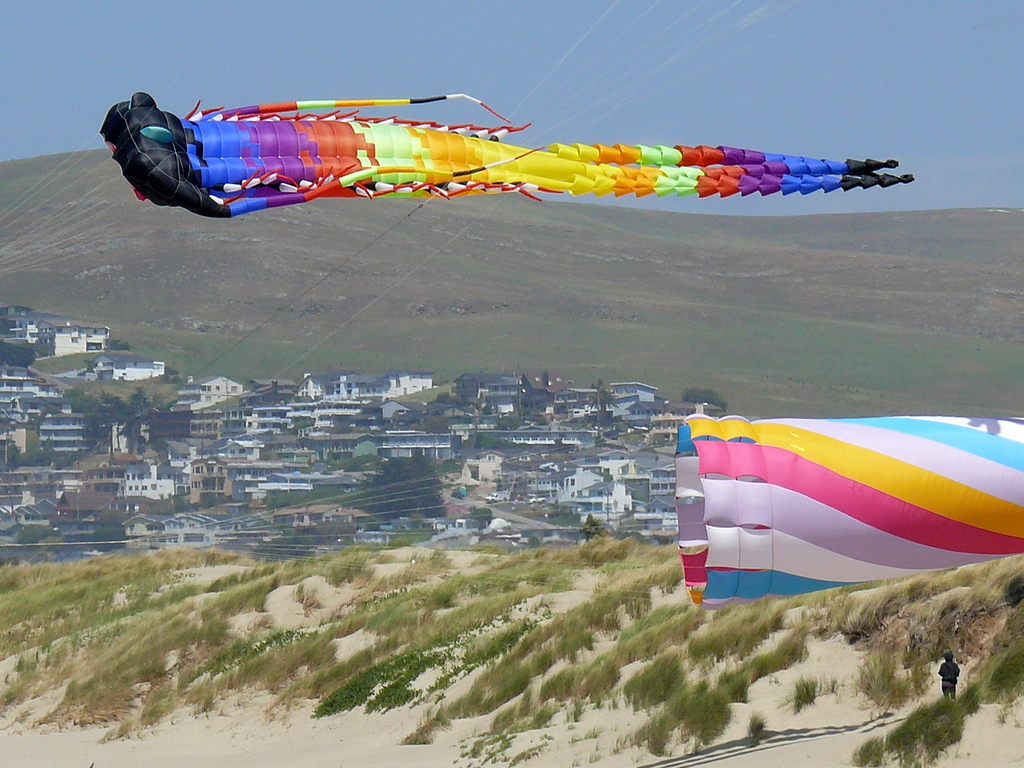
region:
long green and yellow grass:
[505, 681, 578, 716]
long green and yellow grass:
[584, 638, 693, 702]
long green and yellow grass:
[31, 540, 124, 629]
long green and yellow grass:
[280, 634, 398, 707]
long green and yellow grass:
[492, 558, 591, 601]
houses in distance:
[160, 379, 530, 526]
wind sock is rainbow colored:
[99, 80, 937, 227]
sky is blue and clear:
[1, 102, 1019, 219]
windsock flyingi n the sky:
[2, 7, 1021, 217]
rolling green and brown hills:
[4, 146, 1022, 425]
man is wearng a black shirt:
[933, 649, 966, 704]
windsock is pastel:
[671, 405, 1022, 614]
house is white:
[81, 351, 180, 387]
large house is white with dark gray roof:
[298, 360, 439, 405]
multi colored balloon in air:
[633, 316, 1022, 677]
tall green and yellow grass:
[39, 604, 128, 653]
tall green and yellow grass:
[478, 666, 545, 720]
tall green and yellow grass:
[626, 707, 700, 753]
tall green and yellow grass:
[513, 590, 583, 639]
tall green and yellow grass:
[70, 566, 144, 618]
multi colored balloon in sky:
[70, 72, 979, 308]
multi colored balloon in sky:
[649, 394, 1017, 604]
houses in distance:
[134, 414, 420, 507]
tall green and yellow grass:
[643, 701, 771, 727]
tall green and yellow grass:
[880, 657, 994, 762]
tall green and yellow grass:
[61, 634, 189, 707]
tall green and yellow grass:
[251, 549, 373, 666]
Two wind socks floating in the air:
[98, 85, 1021, 608]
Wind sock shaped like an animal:
[91, 85, 921, 229]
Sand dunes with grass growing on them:
[3, 534, 1022, 763]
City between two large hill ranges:
[3, 143, 1016, 758]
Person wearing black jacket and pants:
[934, 647, 963, 706]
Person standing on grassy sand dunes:
[8, 533, 1018, 762]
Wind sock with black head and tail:
[98, 82, 933, 231]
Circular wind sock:
[663, 397, 1021, 622]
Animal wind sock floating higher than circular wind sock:
[97, 86, 1021, 611]